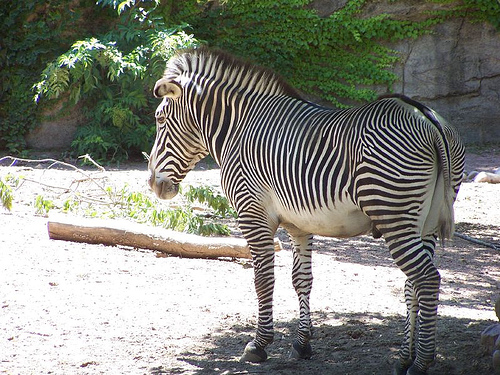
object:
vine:
[206, 0, 432, 103]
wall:
[0, 0, 499, 161]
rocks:
[480, 323, 500, 372]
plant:
[16, 36, 148, 168]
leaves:
[31, 94, 38, 105]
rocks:
[472, 170, 500, 184]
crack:
[423, 88, 482, 102]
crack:
[464, 75, 497, 83]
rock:
[406, 25, 500, 143]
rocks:
[467, 169, 480, 179]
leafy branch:
[0, 153, 236, 237]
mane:
[161, 44, 302, 99]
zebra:
[148, 48, 466, 375]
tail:
[433, 122, 454, 249]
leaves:
[197, 188, 205, 204]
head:
[146, 45, 208, 200]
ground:
[0, 147, 500, 375]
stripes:
[273, 113, 334, 208]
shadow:
[147, 310, 500, 375]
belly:
[279, 197, 371, 238]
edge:
[446, 169, 451, 184]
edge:
[181, 252, 214, 259]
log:
[47, 216, 283, 259]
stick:
[454, 232, 499, 251]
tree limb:
[0, 152, 244, 239]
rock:
[23, 93, 89, 153]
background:
[0, 0, 497, 375]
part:
[54, 274, 139, 372]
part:
[257, 130, 310, 174]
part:
[440, 136, 458, 235]